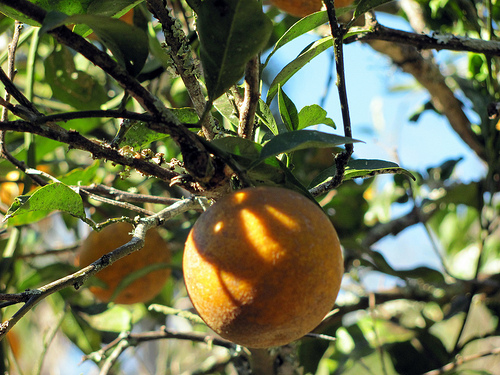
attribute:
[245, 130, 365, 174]
leaf — green 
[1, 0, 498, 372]
tree — green , orange tree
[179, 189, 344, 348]
orange — large 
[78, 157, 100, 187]
leaf — green 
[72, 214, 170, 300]
orange — smaller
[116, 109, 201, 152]
leaf — diseased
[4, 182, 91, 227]
leaf — diseased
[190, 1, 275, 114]
leaves — white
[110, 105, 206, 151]
leaf — green 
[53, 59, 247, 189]
leaf — green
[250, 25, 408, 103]
leaf — tree, green, orange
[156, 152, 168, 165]
bud — flower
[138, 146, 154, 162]
bud — flower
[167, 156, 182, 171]
bud — flower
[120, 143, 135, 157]
bud — flower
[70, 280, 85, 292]
bud — tree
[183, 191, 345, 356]
fruit — orange 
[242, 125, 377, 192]
leaf — green 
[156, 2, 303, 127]
leaf — green, orange, tree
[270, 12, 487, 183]
sky — blue 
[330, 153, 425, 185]
leaf — dark 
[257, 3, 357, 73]
leaf — green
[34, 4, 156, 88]
leaf — green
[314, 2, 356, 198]
branch — small 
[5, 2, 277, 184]
branches — some, dead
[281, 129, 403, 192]
leaf — orange, green, tree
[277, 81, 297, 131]
leaf — green 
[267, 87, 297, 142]
leaf — green 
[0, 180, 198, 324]
branch — brown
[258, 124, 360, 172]
tree leaf — green, orange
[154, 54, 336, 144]
leaf — green 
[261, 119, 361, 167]
leaf — green, orange, tree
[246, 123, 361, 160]
leaf — green